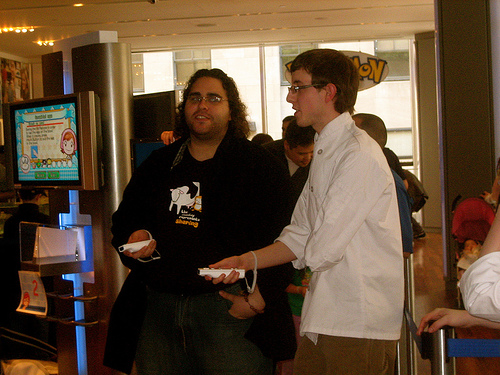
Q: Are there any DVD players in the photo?
A: No, there are no DVD players.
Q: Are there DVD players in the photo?
A: No, there are no DVD players.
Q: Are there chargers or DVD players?
A: No, there are no DVD players or chargers.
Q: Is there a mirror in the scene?
A: No, there are no mirrors.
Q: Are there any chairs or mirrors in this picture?
A: No, there are no mirrors or chairs.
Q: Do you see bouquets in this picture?
A: No, there are no bouquets.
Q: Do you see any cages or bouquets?
A: No, there are no bouquets or cages.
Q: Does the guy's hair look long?
A: Yes, the hair is long.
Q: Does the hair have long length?
A: Yes, the hair is long.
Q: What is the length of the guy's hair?
A: The hair is long.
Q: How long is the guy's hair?
A: The hair is long.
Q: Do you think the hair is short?
A: No, the hair is long.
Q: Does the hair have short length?
A: No, the hair is long.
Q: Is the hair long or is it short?
A: The hair is long.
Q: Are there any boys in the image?
A: No, there are no boys.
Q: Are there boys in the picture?
A: No, there are no boys.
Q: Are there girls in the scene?
A: No, there are no girls.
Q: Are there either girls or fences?
A: No, there are no girls or fences.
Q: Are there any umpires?
A: No, there are no umpires.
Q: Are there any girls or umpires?
A: No, there are no umpires or girls.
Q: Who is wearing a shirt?
A: The guy is wearing a shirt.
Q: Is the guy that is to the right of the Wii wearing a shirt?
A: Yes, the guy is wearing a shirt.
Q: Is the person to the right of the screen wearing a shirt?
A: Yes, the guy is wearing a shirt.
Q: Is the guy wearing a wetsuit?
A: No, the guy is wearing a shirt.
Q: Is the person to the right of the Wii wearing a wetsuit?
A: No, the guy is wearing a shirt.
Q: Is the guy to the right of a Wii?
A: Yes, the guy is to the right of a Wii.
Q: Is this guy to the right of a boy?
A: No, the guy is to the right of a Wii.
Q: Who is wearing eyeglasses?
A: The guy is wearing eyeglasses.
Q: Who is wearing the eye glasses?
A: The guy is wearing eyeglasses.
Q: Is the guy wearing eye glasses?
A: Yes, the guy is wearing eye glasses.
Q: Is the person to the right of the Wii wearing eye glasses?
A: Yes, the guy is wearing eye glasses.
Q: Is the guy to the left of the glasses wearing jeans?
A: No, the guy is wearing eye glasses.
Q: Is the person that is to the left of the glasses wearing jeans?
A: No, the guy is wearing eye glasses.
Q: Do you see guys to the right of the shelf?
A: Yes, there is a guy to the right of the shelf.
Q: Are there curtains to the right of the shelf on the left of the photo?
A: No, there is a guy to the right of the shelf.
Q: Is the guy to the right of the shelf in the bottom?
A: Yes, the guy is to the right of the shelf.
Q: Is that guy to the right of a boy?
A: No, the guy is to the right of the shelf.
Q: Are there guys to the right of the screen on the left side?
A: Yes, there is a guy to the right of the screen.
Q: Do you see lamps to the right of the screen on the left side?
A: No, there is a guy to the right of the screen.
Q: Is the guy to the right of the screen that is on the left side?
A: Yes, the guy is to the right of the screen.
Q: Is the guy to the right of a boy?
A: No, the guy is to the right of the screen.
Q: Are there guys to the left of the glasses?
A: Yes, there is a guy to the left of the glasses.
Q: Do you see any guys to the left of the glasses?
A: Yes, there is a guy to the left of the glasses.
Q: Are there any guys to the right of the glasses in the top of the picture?
A: No, the guy is to the left of the glasses.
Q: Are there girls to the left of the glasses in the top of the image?
A: No, there is a guy to the left of the glasses.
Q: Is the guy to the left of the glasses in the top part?
A: Yes, the guy is to the left of the glasses.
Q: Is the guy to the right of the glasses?
A: No, the guy is to the left of the glasses.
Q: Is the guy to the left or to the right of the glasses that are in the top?
A: The guy is to the left of the glasses.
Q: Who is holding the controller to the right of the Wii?
A: The guy is holding the controller.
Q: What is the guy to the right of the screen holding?
A: The guy is holding the controller.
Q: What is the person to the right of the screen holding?
A: The guy is holding the controller.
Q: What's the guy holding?
A: The guy is holding the controller.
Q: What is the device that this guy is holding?
A: The device is a controller.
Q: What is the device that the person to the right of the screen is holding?
A: The device is a controller.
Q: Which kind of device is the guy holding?
A: The guy is holding the controller.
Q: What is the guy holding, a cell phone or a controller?
A: The guy is holding a controller.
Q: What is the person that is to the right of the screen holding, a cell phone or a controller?
A: The guy is holding a controller.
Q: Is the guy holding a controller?
A: Yes, the guy is holding a controller.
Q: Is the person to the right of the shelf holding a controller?
A: Yes, the guy is holding a controller.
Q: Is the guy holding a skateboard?
A: No, the guy is holding a controller.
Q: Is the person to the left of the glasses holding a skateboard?
A: No, the guy is holding a controller.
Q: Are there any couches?
A: No, there are no couches.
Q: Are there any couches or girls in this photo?
A: No, there are no couches or girls.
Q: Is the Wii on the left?
A: Yes, the Wii is on the left of the image.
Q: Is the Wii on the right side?
A: No, the Wii is on the left of the image.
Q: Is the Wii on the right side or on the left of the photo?
A: The Wii is on the left of the image.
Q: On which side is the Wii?
A: The Wii is on the left of the image.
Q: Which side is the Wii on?
A: The Wii is on the left of the image.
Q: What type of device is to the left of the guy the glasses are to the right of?
A: The device is a Wii.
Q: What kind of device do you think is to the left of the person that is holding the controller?
A: The device is a Wii.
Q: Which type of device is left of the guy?
A: The device is a Wii.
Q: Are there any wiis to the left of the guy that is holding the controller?
A: Yes, there is a Wii to the left of the guy.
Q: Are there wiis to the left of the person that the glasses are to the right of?
A: Yes, there is a Wii to the left of the guy.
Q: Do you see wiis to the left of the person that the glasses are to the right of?
A: Yes, there is a Wii to the left of the guy.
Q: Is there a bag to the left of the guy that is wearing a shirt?
A: No, there is a Wii to the left of the guy.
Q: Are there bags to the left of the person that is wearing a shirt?
A: No, there is a Wii to the left of the guy.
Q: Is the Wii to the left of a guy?
A: Yes, the Wii is to the left of a guy.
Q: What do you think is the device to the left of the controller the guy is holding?
A: The device is a Wii.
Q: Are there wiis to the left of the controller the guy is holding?
A: Yes, there is a Wii to the left of the controller.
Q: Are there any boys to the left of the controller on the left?
A: No, there is a Wii to the left of the controller.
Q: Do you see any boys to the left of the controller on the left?
A: No, there is a Wii to the left of the controller.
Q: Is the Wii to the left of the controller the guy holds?
A: Yes, the Wii is to the left of the controller.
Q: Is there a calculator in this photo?
A: No, there are no calculators.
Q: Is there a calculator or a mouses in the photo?
A: No, there are no calculators or computer mousess.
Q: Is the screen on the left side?
A: Yes, the screen is on the left of the image.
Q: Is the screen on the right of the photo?
A: No, the screen is on the left of the image.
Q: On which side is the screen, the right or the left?
A: The screen is on the left of the image.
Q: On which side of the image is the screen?
A: The screen is on the left of the image.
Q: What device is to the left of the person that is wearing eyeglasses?
A: The device is a screen.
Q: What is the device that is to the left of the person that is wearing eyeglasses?
A: The device is a screen.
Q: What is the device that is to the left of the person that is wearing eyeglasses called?
A: The device is a screen.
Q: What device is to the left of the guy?
A: The device is a screen.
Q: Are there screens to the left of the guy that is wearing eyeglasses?
A: Yes, there is a screen to the left of the guy.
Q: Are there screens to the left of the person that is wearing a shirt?
A: Yes, there is a screen to the left of the guy.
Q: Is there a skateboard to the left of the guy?
A: No, there is a screen to the left of the guy.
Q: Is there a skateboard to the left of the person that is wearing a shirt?
A: No, there is a screen to the left of the guy.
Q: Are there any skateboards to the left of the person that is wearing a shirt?
A: No, there is a screen to the left of the guy.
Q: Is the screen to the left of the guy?
A: Yes, the screen is to the left of the guy.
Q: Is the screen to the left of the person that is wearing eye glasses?
A: Yes, the screen is to the left of the guy.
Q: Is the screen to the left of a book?
A: No, the screen is to the left of the guy.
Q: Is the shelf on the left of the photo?
A: Yes, the shelf is on the left of the image.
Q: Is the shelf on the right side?
A: No, the shelf is on the left of the image.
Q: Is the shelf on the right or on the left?
A: The shelf is on the left of the image.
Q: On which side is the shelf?
A: The shelf is on the left of the image.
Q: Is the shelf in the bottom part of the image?
A: Yes, the shelf is in the bottom of the image.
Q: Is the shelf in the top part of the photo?
A: No, the shelf is in the bottom of the image.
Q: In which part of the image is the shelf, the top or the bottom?
A: The shelf is in the bottom of the image.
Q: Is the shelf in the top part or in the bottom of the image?
A: The shelf is in the bottom of the image.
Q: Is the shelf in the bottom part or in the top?
A: The shelf is in the bottom of the image.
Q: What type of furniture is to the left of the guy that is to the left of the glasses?
A: The piece of furniture is a shelf.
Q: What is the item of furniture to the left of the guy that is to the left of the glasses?
A: The piece of furniture is a shelf.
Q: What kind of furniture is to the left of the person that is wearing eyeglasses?
A: The piece of furniture is a shelf.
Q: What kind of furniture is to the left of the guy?
A: The piece of furniture is a shelf.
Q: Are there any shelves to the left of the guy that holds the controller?
A: Yes, there is a shelf to the left of the guy.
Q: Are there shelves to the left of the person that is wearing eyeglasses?
A: Yes, there is a shelf to the left of the guy.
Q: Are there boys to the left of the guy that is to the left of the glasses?
A: No, there is a shelf to the left of the guy.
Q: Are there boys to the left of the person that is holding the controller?
A: No, there is a shelf to the left of the guy.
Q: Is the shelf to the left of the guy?
A: Yes, the shelf is to the left of the guy.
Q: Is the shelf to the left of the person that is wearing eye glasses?
A: Yes, the shelf is to the left of the guy.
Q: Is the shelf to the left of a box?
A: No, the shelf is to the left of the guy.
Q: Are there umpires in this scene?
A: No, there are no umpires.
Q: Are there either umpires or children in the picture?
A: No, there are no umpires or children.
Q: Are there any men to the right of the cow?
A: Yes, there is a man to the right of the cow.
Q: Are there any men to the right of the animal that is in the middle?
A: Yes, there is a man to the right of the cow.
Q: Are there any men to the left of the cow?
A: No, the man is to the right of the cow.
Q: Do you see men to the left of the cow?
A: No, the man is to the right of the cow.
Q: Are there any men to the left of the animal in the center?
A: No, the man is to the right of the cow.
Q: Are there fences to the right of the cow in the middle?
A: No, there is a man to the right of the cow.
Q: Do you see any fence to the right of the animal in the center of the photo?
A: No, there is a man to the right of the cow.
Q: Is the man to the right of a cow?
A: Yes, the man is to the right of a cow.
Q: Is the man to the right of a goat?
A: No, the man is to the right of a cow.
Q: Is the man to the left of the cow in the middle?
A: No, the man is to the right of the cow.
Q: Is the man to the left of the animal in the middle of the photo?
A: No, the man is to the right of the cow.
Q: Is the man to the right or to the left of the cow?
A: The man is to the right of the cow.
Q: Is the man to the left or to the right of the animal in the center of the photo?
A: The man is to the right of the cow.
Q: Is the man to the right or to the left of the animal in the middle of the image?
A: The man is to the right of the cow.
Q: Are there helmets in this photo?
A: No, there are no helmets.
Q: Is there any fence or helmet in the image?
A: No, there are no helmets or fences.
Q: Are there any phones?
A: No, there are no phones.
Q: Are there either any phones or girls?
A: No, there are no phones or girls.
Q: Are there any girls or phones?
A: No, there are no phones or girls.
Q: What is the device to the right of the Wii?
A: The device is a controller.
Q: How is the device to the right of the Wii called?
A: The device is a controller.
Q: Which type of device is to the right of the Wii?
A: The device is a controller.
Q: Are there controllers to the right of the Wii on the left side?
A: Yes, there is a controller to the right of the Wii.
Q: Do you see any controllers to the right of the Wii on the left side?
A: Yes, there is a controller to the right of the Wii.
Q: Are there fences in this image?
A: No, there are no fences.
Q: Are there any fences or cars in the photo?
A: No, there are no fences or cars.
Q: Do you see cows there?
A: Yes, there is a cow.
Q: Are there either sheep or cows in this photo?
A: Yes, there is a cow.